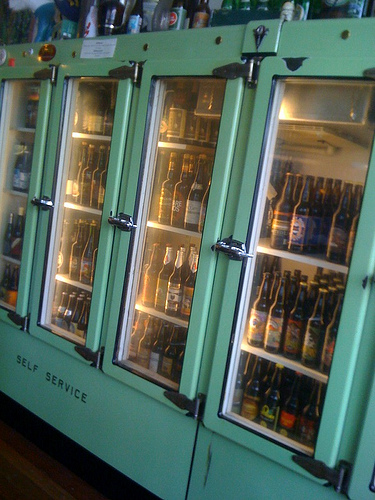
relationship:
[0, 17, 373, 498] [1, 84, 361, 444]
cooler filled with beer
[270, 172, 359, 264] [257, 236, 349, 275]
bottles are on a shelf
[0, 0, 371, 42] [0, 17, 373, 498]
bottles sitting on cooler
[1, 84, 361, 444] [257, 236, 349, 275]
beer are on shelf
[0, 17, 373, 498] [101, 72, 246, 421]
cooler has door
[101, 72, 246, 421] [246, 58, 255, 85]
door has hinge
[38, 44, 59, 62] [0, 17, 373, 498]
seal on cooler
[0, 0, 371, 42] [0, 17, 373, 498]
bottles on top of cooler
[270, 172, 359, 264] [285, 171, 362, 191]
bottles have lids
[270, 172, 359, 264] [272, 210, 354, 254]
bottles have labels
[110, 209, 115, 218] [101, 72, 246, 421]
keyhold on door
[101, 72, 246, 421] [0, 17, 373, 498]
door on cooler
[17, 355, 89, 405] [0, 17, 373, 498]
letters on front of cooler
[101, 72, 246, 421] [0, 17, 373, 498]
door on front of cooler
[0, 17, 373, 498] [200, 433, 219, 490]
cooler has scuff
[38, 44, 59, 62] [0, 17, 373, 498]
seal on front of cooler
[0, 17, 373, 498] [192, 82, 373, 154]
cooler has unit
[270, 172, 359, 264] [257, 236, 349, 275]
bottles are on shelf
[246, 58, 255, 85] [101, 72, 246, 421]
hinge on door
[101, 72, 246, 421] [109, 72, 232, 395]
door has window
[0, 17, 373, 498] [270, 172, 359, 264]
cooler full of bottles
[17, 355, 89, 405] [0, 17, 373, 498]
letters are on front of cooler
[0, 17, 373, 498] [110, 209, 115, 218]
cooler has keyhold